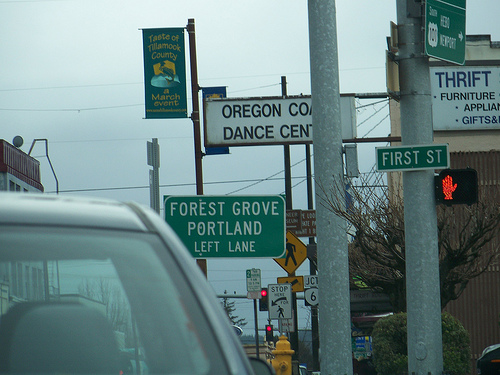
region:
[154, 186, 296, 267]
Green street sign on pole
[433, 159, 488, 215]
Pedestrian sign with a stop hand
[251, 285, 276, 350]
Two traffic lights on red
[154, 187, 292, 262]
Green sign with white words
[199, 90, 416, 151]
White sign fixed in a pole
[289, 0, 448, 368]
Two poles holding street signs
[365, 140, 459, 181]
Small sign saying "First ST"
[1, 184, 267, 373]
Car with black sit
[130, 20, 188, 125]
Flag on pole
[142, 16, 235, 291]
Pole holding two signs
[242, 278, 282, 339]
red signal light is seen.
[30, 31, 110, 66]
sky is blue in color.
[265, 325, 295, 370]
pump is yellow in color.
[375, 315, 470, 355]
plants are green in color.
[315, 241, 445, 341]
poles are grey in color.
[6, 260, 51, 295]
windows are white in color.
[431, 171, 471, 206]
stop sign is glowing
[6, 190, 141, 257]
grey color car is seen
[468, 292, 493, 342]
wall is red in color.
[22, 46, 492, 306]
daytime picture.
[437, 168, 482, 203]
A red hand street light.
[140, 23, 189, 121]
A Tillamock County banner sign.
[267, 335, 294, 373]
A yellow fire hydrant.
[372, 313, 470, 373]
A green bush behind pole.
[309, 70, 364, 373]
A utility pole in the area.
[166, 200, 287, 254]
A green and white Forest Grove Portland sign.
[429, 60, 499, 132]
A Thrift store sign.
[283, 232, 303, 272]
Part of a pedestrian walking sign.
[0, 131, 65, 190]
The top of a building.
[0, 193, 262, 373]
The window of a vehicle.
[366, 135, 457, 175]
a green and white street sign on a pole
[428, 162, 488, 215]
a don't walk signal on a pole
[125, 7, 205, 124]
an event sign on a pole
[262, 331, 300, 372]
a yellow fire hydrant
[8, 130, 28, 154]
a satellite dish on top of a building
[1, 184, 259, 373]
the window of a car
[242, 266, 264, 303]
a parking time limit sign on a pole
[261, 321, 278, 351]
a traffic signal with a red light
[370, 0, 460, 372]
a pole with several signs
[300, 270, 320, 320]
a junction sign on a pole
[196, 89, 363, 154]
a place to dance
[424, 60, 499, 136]
a place for recycling without repurposing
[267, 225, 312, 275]
caution because pedestrians may appear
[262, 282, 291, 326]
information that drivers should stop instead of hitting pedestrians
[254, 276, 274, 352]
red lights in tandem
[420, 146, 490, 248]
a right hand meaning don't walk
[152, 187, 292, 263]
directions to another location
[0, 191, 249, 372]
back window of a car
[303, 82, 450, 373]
two sturdy poles